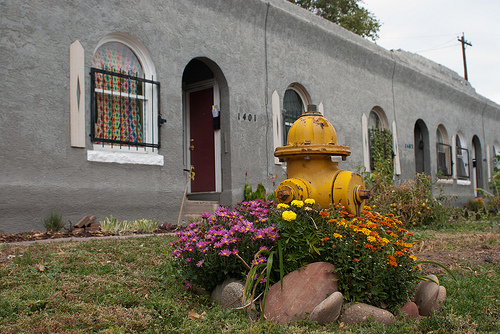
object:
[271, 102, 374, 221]
hydrant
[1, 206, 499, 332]
yard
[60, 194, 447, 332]
garden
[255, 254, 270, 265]
flowers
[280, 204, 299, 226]
marigolds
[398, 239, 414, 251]
flowers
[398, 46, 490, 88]
stone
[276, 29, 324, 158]
windows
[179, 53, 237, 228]
archway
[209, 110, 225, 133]
mailbox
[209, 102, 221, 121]
mail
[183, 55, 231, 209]
wall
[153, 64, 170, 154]
bars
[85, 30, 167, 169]
window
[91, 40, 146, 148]
curtains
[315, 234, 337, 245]
flowers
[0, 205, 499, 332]
ground vegitation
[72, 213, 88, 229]
bricks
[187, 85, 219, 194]
door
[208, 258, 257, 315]
rocks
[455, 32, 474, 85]
pole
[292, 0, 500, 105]
sky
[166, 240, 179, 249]
flowers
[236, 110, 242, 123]
numbers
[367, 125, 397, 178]
greenery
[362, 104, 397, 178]
window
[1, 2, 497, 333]
front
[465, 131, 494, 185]
shutter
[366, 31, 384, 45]
leaves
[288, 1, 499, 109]
background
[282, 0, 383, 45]
tree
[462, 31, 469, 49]
wires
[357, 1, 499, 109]
air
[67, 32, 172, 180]
frames